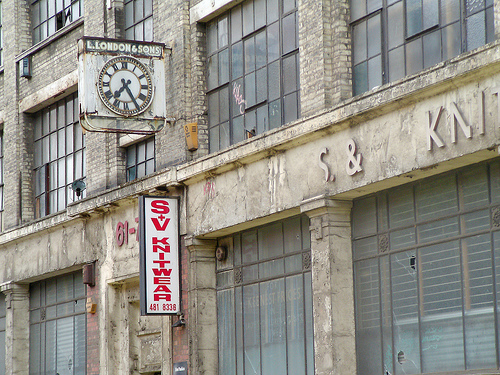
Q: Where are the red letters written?
A: On a white sign.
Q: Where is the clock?
A: On a building.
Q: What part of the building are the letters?
A: On the front.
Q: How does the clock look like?
A: Old and worn out.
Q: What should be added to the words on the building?
A: Missing letters.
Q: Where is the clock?
A: ON the side of the building.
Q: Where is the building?
A: Beside the road.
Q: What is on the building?
A: Windows.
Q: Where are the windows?
A: On the building.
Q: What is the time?
A: 7:25.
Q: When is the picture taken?
A: Daytime.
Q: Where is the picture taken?
A: By the side of a building.